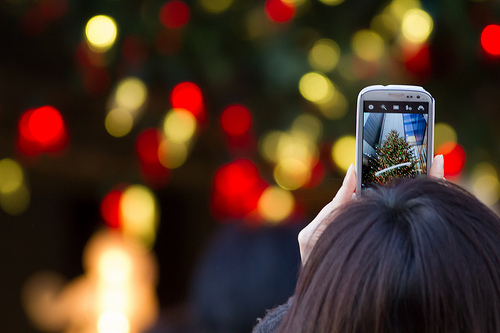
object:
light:
[26, 95, 64, 147]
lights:
[83, 10, 118, 51]